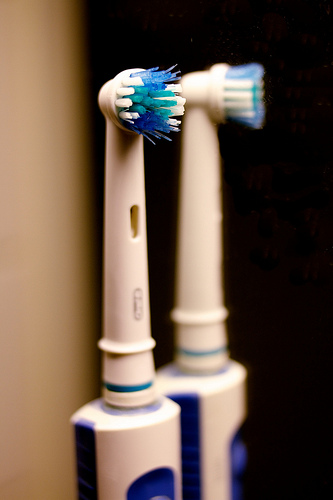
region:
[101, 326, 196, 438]
a battery operated toothbrush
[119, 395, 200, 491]
a battery operated toothbrush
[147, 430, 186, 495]
a battery operated toothbrush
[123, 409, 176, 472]
a battery operated toothbrush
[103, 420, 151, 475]
a battery operated toothbrush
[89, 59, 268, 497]
two electric toothbrushes standing upright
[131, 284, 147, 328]
oral b logo on side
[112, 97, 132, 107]
set of bristles on brush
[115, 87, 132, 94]
set of bristles on brush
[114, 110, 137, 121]
set of bristles on brush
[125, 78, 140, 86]
set of bristles on brush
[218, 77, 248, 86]
set of bristles on brush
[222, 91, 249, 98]
set of bristles on brush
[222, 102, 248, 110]
set of bristles on brush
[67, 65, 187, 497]
an electric toothbrush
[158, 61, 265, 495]
an electric toothbrush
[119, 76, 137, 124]
white toothbrush head bristles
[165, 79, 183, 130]
white toothbrush head bristles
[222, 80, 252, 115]
white toothbrush head bristles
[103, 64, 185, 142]
round spinning tooth brush head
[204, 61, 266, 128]
round spinning tooth brush head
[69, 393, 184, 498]
a white a blue toothbrush handle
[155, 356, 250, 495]
a white a blue toothbrush handle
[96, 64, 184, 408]
a removable tooth brush head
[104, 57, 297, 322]
toothbrush heads on brushes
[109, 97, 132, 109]
bristles on toothbrush head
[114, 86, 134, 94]
bristles on toothbrush head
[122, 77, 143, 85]
bristles on toothbrush head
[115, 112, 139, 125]
bristles on toothbrush head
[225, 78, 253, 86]
bristles on toothbrush head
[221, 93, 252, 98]
bristles on toothbrush head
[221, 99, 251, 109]
bristles on toothbrush head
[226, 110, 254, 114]
bristles on toothbrush head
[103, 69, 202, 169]
The bristles are white and blue.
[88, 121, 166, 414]
The neck is white.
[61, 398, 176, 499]
The handle is white and blue.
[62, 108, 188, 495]
The toothbrush is blue and white.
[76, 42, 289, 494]
Two toothbrushes are standing up.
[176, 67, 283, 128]
The head is white.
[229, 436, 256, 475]
The button is blue.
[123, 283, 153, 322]
The logo is on the neck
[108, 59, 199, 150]
Some bristles are sticking up.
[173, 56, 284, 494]
The toothbrush is out of focus.